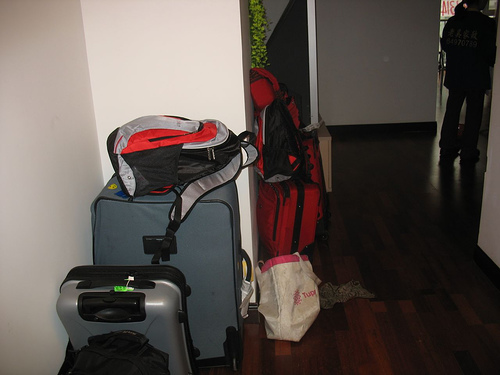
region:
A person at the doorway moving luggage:
[433, 3, 498, 177]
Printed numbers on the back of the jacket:
[443, 25, 481, 48]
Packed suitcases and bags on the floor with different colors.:
[53, 64, 325, 374]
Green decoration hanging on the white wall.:
[247, 0, 269, 69]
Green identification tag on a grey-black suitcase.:
[111, 273, 138, 293]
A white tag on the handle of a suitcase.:
[231, 244, 256, 320]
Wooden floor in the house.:
[380, 139, 437, 368]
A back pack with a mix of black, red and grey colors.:
[103, 109, 261, 207]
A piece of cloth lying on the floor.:
[319, 275, 377, 312]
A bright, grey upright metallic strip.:
[306, 0, 320, 127]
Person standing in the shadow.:
[427, 3, 487, 180]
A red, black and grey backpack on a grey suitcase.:
[102, 103, 257, 219]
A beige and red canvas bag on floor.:
[255, 250, 330, 340]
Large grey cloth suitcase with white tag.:
[91, 170, 246, 353]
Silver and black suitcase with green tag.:
[56, 256, 198, 367]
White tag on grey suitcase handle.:
[236, 271, 255, 318]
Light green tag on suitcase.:
[108, 280, 142, 296]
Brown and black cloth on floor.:
[320, 275, 373, 312]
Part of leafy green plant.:
[247, 0, 271, 67]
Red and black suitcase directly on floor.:
[259, 187, 323, 255]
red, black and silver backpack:
[106, 113, 261, 199]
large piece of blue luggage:
[93, 175, 253, 356]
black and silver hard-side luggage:
[57, 260, 197, 373]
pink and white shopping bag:
[255, 252, 322, 344]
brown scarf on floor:
[321, 278, 374, 313]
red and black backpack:
[251, 65, 308, 182]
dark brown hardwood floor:
[342, 136, 466, 371]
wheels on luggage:
[228, 353, 244, 371]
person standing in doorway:
[438, 0, 497, 174]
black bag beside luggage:
[56, 330, 173, 370]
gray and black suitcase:
[45, 272, 192, 355]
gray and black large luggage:
[91, 175, 255, 304]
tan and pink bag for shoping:
[268, 239, 322, 373]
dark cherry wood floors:
[352, 220, 449, 344]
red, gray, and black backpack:
[97, 121, 245, 220]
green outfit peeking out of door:
[250, 3, 298, 78]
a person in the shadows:
[441, 4, 483, 175]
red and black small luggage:
[271, 188, 346, 272]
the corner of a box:
[320, 131, 347, 206]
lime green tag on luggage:
[110, 280, 163, 308]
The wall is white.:
[0, 0, 257, 372]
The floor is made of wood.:
[199, 66, 495, 373]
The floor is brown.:
[195, 58, 499, 374]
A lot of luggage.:
[57, 66, 322, 371]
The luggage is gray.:
[91, 168, 243, 363]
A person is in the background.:
[436, 0, 498, 165]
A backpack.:
[107, 112, 258, 224]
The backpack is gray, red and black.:
[106, 113, 261, 224]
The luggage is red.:
[248, 66, 326, 258]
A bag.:
[253, 253, 322, 343]